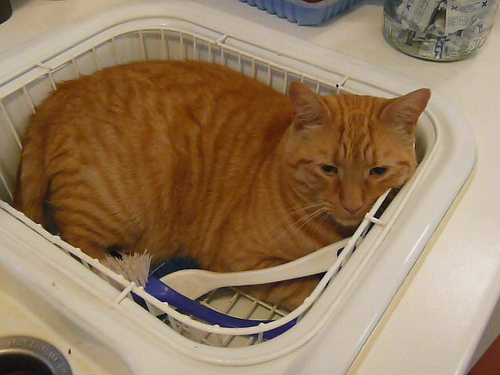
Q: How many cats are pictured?
A: One.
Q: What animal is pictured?
A: A cat.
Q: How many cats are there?
A: One.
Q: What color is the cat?
A: Orange.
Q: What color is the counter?
A: White.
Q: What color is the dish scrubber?
A: Blue.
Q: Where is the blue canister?
A: Behind the cat.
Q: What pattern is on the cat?
A: Stripes.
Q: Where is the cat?
A: In the drying rack.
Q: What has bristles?
A: The dish scrubber.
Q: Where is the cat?
A: Sink.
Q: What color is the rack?
A: White.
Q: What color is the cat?
A: Orange.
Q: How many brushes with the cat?
A: Two.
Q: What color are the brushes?
A: White and blue.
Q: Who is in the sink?
A: Cat.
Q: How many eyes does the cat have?
A: Two.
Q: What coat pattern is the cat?
A: Stripes.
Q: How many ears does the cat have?
A: Two.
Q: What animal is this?
A: Cat.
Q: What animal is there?
A: Cat.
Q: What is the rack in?
A: Sink.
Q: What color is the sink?
A: White.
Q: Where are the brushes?
A: In the rack.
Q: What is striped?
A: Cat.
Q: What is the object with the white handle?
A: A brush.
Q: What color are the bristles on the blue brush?
A: White.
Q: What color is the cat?
A: Orange.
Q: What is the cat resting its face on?
A: A basket.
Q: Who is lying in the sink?
A: A cat.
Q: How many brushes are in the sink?
A: Two.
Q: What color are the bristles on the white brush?
A: Black.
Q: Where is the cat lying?
A: In a sink.